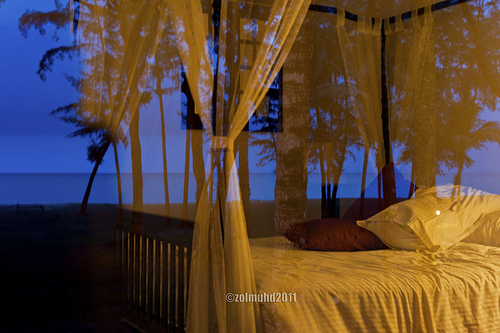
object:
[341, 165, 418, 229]
red pillow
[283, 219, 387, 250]
pillow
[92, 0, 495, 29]
canopy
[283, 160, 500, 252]
pillows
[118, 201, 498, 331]
bed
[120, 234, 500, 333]
sheet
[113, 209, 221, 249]
rail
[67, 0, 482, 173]
netting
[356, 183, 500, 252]
pillow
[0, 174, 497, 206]
ocean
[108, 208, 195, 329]
wooden footboard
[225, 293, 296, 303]
watermark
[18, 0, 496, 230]
trees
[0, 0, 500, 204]
sky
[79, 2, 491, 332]
canopy cover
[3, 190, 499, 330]
beach